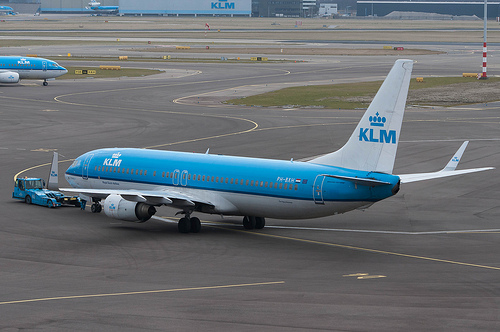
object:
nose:
[62, 150, 82, 183]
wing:
[57, 187, 211, 206]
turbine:
[104, 194, 158, 224]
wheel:
[241, 216, 265, 230]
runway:
[0, 232, 498, 332]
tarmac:
[0, 221, 497, 331]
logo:
[369, 110, 386, 126]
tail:
[324, 58, 435, 196]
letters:
[358, 127, 396, 143]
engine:
[102, 193, 157, 223]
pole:
[477, 0, 488, 80]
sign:
[114, 0, 256, 15]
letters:
[210, 0, 236, 9]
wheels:
[91, 203, 103, 213]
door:
[311, 174, 327, 204]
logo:
[112, 153, 120, 158]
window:
[193, 174, 196, 180]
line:
[260, 224, 500, 274]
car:
[11, 178, 84, 208]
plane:
[56, 60, 497, 233]